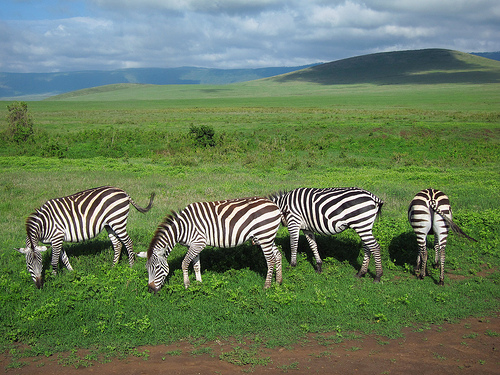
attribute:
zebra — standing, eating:
[13, 180, 161, 292]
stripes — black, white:
[52, 200, 102, 231]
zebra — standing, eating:
[143, 195, 287, 295]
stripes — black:
[198, 205, 255, 238]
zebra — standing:
[252, 181, 389, 284]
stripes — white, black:
[294, 196, 355, 224]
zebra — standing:
[407, 186, 456, 286]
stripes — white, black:
[411, 191, 449, 225]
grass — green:
[1, 48, 499, 352]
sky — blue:
[2, 3, 499, 81]